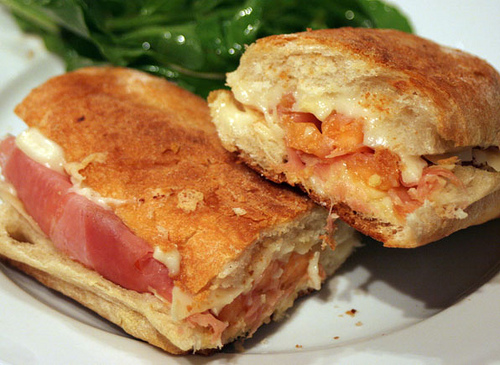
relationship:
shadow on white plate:
[357, 222, 497, 316] [1, 48, 497, 354]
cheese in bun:
[286, 87, 428, 188] [205, 22, 498, 248]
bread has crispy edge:
[202, 10, 484, 252] [321, 195, 393, 241]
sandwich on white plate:
[1, 65, 364, 359] [21, 256, 496, 361]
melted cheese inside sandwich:
[8, 124, 82, 191] [0, 65, 255, 347]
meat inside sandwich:
[19, 178, 149, 281] [22, 62, 325, 331]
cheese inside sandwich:
[12, 129, 67, 181] [22, 62, 325, 331]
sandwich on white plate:
[10, 34, 498, 352] [1, 48, 497, 354]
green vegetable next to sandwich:
[0, 0, 413, 99] [198, 28, 497, 248]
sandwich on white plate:
[206, 27, 500, 248] [1, 48, 497, 354]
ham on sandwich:
[3, 144, 174, 299] [1, 65, 364, 359]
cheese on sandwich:
[344, 101, 425, 182] [201, 21, 499, 269]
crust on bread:
[16, 65, 311, 287] [12, 63, 336, 294]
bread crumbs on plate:
[346, 307, 368, 329] [239, 257, 491, 363]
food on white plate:
[111, 110, 380, 327] [1, 48, 497, 354]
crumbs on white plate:
[298, 285, 434, 350] [1, 48, 497, 354]